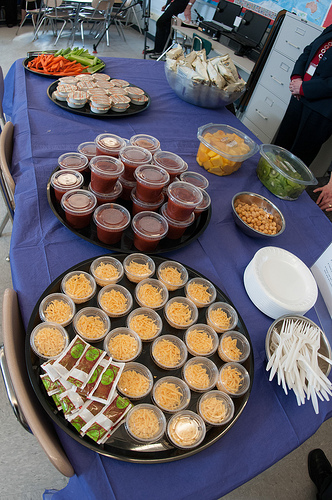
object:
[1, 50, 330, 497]
table cover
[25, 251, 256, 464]
tray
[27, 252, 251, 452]
cheese cups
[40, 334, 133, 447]
sauce packets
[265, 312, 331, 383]
bowl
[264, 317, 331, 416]
forks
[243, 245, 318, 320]
plates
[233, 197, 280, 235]
chickpeas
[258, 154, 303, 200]
kiwi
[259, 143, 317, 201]
plastic dish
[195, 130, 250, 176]
mangoes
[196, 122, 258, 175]
plastic dish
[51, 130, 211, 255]
sauce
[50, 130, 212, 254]
small dishes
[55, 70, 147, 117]
peanut butter cups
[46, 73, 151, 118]
tray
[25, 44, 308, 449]
food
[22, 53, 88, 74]
carrots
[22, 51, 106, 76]
plate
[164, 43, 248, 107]
snacks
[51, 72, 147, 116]
dip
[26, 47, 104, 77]
veggies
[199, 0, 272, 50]
computers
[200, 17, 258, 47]
keyboards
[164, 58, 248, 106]
bowl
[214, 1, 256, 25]
headphones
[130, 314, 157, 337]
cheese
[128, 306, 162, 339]
container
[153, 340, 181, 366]
cheese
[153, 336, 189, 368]
container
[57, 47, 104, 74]
celery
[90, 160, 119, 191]
salsa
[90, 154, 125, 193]
container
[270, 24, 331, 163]
person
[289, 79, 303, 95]
hands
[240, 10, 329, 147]
cabinet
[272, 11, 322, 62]
drawer